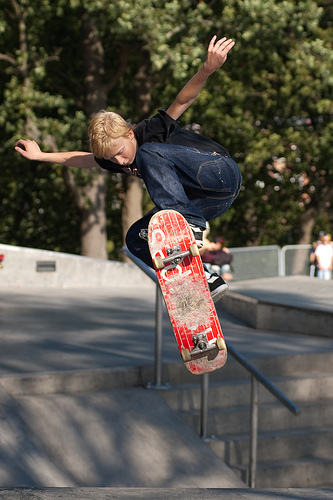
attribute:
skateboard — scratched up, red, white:
[145, 210, 233, 381]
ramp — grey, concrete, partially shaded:
[1, 383, 255, 487]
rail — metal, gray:
[121, 244, 300, 495]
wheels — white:
[211, 336, 225, 351]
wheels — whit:
[179, 344, 194, 367]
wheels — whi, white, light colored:
[187, 239, 200, 257]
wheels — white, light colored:
[154, 254, 164, 272]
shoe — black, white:
[198, 266, 233, 305]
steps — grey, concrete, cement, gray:
[153, 353, 331, 487]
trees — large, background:
[1, 0, 305, 264]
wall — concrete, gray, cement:
[2, 242, 159, 294]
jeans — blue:
[134, 134, 243, 225]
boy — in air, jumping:
[14, 34, 245, 302]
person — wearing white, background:
[311, 231, 332, 284]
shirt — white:
[314, 241, 332, 270]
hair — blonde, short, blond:
[89, 108, 132, 161]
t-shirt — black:
[89, 104, 236, 185]